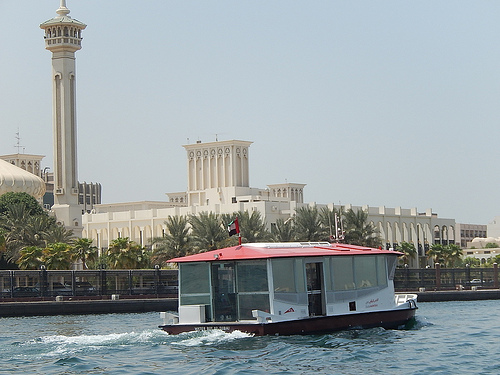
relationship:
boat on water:
[156, 245, 419, 338] [4, 302, 499, 372]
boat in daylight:
[156, 245, 419, 338] [2, 2, 497, 372]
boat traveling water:
[156, 245, 419, 338] [4, 302, 499, 372]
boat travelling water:
[156, 245, 419, 338] [4, 302, 499, 372]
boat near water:
[156, 245, 419, 338] [4, 302, 499, 372]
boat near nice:
[156, 245, 419, 338] [1, 0, 497, 290]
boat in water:
[156, 245, 419, 338] [104, 311, 467, 354]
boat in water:
[148, 225, 426, 346] [6, 311, 498, 372]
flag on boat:
[230, 209, 244, 249] [156, 245, 419, 338]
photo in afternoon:
[17, 13, 467, 356] [6, 0, 498, 290]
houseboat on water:
[150, 233, 437, 342] [42, 309, 447, 361]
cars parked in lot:
[4, 280, 172, 290] [2, 273, 192, 303]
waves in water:
[23, 332, 245, 362] [37, 303, 477, 370]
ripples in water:
[438, 310, 485, 337] [12, 302, 462, 364]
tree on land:
[20, 223, 81, 288] [6, 276, 173, 299]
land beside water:
[6, 276, 173, 299] [12, 302, 462, 364]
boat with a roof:
[156, 245, 419, 338] [166, 236, 409, 271]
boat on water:
[156, 245, 419, 338] [30, 306, 464, 366]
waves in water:
[53, 350, 85, 368] [12, 302, 462, 364]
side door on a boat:
[303, 260, 328, 322] [156, 245, 419, 338]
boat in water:
[156, 245, 419, 338] [30, 306, 464, 366]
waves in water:
[444, 340, 471, 357] [37, 303, 477, 370]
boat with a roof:
[156, 245, 419, 338] [165, 225, 413, 265]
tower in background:
[41, 12, 91, 293] [31, 28, 456, 233]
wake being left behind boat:
[39, 325, 260, 359] [156, 245, 419, 338]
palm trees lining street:
[14, 195, 447, 261] [2, 270, 462, 301]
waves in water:
[23, 329, 259, 355] [12, 302, 462, 364]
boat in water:
[156, 245, 419, 338] [76, 291, 475, 368]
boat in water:
[156, 245, 419, 338] [41, 305, 497, 362]